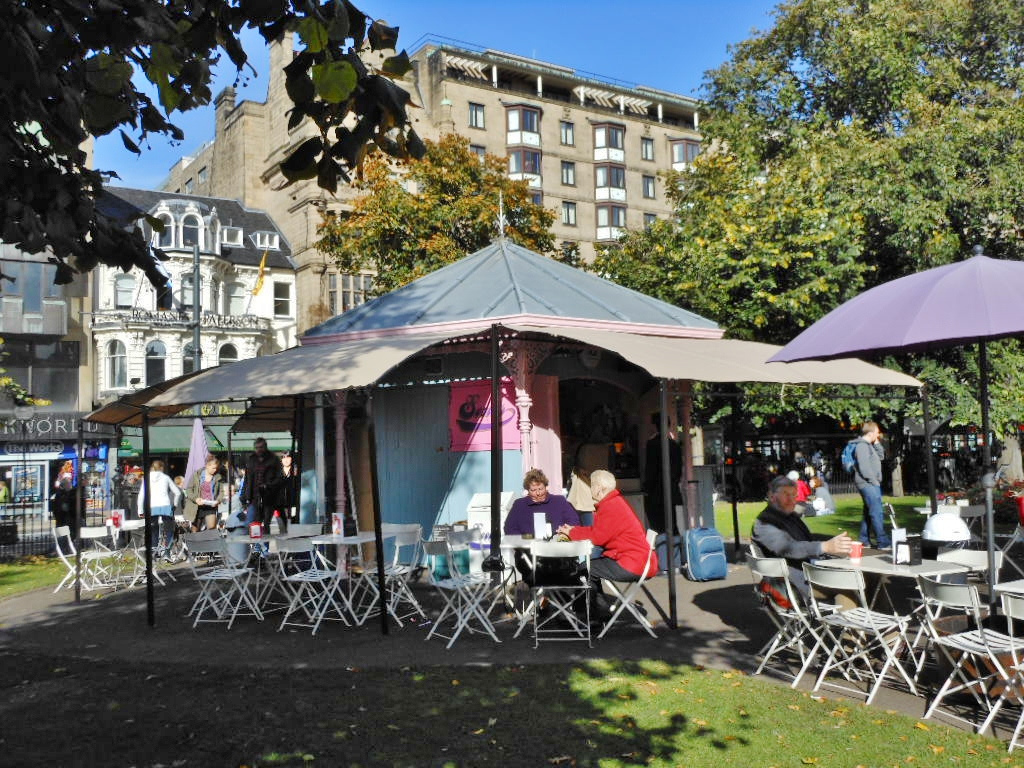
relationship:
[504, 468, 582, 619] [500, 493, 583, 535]
person wearing jacket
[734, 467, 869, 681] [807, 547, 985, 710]
man sitting at table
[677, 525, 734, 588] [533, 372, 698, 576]
backpack leaning against wall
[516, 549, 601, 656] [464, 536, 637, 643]
chair at table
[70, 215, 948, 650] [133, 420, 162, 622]
building with pole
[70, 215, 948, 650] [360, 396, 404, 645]
building with pole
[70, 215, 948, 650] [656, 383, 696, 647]
building with pole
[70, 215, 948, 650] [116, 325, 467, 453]
building with awning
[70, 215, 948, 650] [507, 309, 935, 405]
building with awning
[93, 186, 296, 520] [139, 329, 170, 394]
building with window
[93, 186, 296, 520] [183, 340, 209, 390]
building with window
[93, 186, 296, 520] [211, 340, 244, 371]
building with window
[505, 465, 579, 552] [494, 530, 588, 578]
person at table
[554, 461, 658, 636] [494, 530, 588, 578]
person at table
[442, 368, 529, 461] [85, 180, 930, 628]
sign on tent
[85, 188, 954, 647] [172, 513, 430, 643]
chairs under tent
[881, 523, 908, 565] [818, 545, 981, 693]
napkins on table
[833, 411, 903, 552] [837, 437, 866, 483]
man wearing backpack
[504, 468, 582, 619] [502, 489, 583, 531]
person wearing shirt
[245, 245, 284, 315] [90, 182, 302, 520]
flag hanging off building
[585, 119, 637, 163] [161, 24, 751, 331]
window on building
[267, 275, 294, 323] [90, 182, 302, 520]
window on building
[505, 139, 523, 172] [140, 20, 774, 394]
window on building